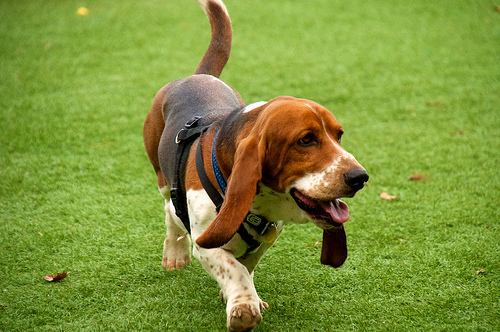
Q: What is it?
A: Dog.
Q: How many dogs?
A: 1.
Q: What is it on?
A: Grass.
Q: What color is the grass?
A: Green.